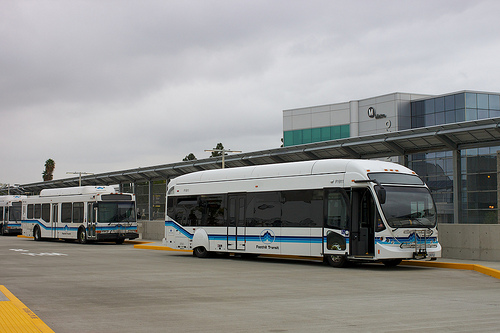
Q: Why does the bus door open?
A: To let passengers on and off.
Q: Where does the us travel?
A: On the roadway.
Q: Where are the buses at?
A: At the bus terminal?.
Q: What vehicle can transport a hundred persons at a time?
A: A bus.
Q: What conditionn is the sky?
A: Cloudy.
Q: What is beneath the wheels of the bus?
A: The ground.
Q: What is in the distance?
A: The green and white building.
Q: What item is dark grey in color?
A: The pavement.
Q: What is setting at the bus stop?
A: The bus.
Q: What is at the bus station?
A: Three white and blue buses.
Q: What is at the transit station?
A: The gray paved bus alley.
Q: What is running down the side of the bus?
A: The tinted windows.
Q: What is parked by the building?
A: The buses.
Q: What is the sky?
A: Heavily overcast.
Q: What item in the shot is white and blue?
A: The bus.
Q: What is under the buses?
A: The grey concrete.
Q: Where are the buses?
A: Parking lot.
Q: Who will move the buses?
A: Driver.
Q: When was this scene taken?
A: Yesterday.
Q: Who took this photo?
A: A tourist.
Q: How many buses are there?
A: Two.